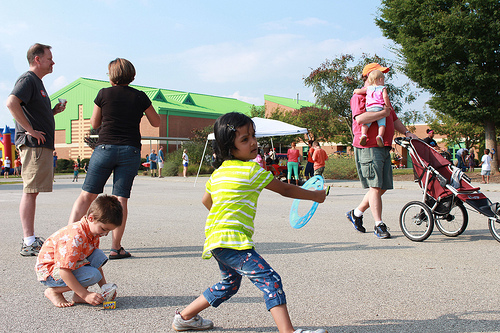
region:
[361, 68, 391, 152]
Baby girl with pink and blue outfit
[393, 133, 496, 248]
Red and black stroller with 3 wheels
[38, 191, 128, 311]
Boy do not have shoes on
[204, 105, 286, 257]
Little girl with white and green shirt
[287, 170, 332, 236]
Light blue frisbee in hand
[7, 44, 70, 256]
Man is holding a cup in hand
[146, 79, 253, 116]
Lime green roof on building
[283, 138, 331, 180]
People in the background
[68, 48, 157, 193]
Woman with black shirt and blue jeans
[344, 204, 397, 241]
Black nike tennis shoes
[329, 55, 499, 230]
man pushing red stroller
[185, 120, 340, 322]
young girl holding blue frisbee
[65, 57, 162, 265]
woman wearing black shirt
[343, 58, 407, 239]
man carrying a young child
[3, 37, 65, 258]
man wearing light brown shorts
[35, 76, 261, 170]
building with green roof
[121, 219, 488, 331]
shadows of people on the pavement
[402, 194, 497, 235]
three wheels on the stroller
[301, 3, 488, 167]
trees on the right side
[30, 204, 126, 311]
child kneeling down on the pavement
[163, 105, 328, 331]
little girl with a blue frisbee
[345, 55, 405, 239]
man carrying a small child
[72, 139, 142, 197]
super tight denim shorts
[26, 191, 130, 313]
little boy with bare feet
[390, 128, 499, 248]
red stroller with large wheels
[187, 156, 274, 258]
fluorescent yellow and white striped shirt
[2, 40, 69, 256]
man wearing khaki shorts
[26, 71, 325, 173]
large building with a green roof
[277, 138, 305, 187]
person wearing a red shirt and green pants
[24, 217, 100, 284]
small orange button up shirt with a collar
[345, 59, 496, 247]
Man with baby and stroller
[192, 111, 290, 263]
Little girl wearing yellow and white striped shirt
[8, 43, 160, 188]
Man and woman talking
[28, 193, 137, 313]
Little boy playing on ground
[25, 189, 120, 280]
Little boy wearing orange shirt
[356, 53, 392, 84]
Man wearing orange cap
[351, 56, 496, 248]
Man pushing red stroller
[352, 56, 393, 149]
Man carrying a baby girl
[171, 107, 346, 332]
Little girl wearing blue pants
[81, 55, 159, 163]
Lady is wearing black shirt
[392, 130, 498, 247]
An empty baby stroller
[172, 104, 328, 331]
A young girl about to throw a frisbee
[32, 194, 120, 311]
A young boy with a bag of candy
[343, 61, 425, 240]
A man pushing an empty baby stroller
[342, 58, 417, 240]
A man holding a baby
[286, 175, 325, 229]
A blue frisbee about to be thrown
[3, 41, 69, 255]
A man standing and holding a drink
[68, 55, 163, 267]
A lady standing with her back turned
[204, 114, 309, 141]
The white roof of a tent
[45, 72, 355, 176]
A building with a green roof